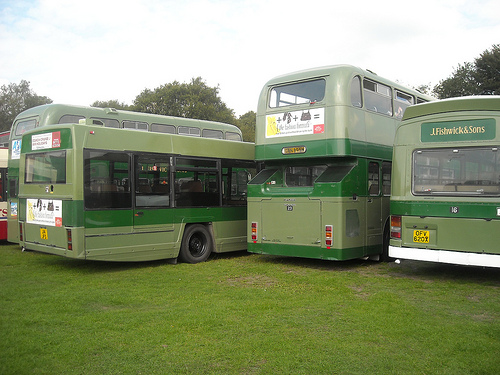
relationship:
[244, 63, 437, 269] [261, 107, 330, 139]
busses have sign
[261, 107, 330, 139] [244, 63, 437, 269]
sign on busses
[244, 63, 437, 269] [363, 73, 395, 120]
busses have windows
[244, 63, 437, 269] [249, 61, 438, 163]
busses have levels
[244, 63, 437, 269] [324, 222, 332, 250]
busses have taillights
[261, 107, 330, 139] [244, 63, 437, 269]
sign on back of busses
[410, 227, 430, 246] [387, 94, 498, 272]
license plate on vehicle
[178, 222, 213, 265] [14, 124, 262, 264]
tire on bus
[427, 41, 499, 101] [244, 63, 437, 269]
trees are above busses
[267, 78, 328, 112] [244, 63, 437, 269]
window on busses